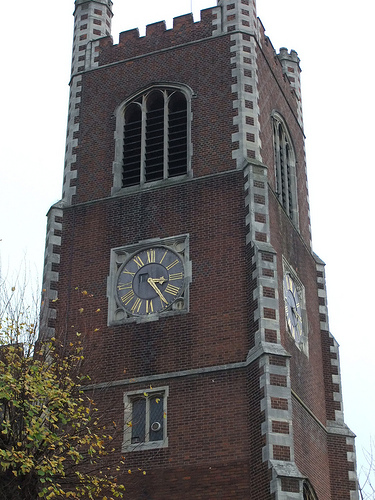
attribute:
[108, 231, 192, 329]
clock — grey, gold, square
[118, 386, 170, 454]
window — small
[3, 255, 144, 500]
tree — green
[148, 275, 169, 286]
clock hand — gold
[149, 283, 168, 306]
clock hand — gold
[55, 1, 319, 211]
tower — brick, large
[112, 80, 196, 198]
window — grey, tall, large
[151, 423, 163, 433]
object — round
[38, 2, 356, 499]
building — brick, tall, older, old